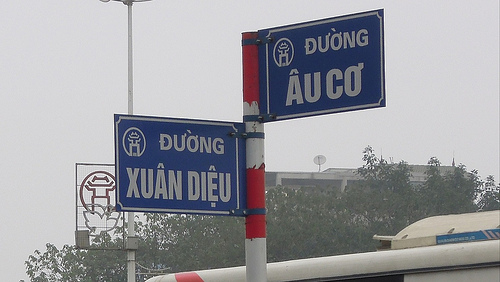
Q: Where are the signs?
A: On the pole.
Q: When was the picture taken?
A: Daytime.